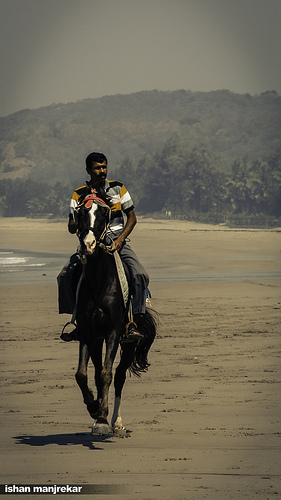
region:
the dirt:
[158, 381, 274, 474]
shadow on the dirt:
[15, 430, 80, 456]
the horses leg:
[73, 368, 132, 434]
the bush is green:
[154, 147, 230, 198]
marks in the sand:
[171, 319, 260, 417]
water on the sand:
[6, 255, 41, 277]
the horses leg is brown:
[100, 356, 116, 424]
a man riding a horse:
[72, 149, 124, 208]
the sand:
[181, 246, 257, 272]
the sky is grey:
[113, 57, 192, 78]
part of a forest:
[239, 177, 245, 190]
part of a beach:
[170, 442, 180, 459]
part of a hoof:
[110, 424, 113, 431]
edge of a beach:
[172, 425, 182, 456]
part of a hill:
[169, 456, 177, 472]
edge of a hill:
[184, 423, 200, 463]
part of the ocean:
[187, 408, 191, 414]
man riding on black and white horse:
[49, 148, 156, 439]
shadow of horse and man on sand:
[8, 430, 111, 457]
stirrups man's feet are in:
[59, 316, 140, 342]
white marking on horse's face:
[83, 200, 101, 232]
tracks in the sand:
[10, 307, 276, 474]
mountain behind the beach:
[14, 79, 280, 188]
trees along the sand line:
[11, 147, 276, 222]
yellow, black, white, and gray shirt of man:
[67, 185, 132, 241]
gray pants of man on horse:
[53, 233, 150, 314]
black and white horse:
[55, 187, 165, 433]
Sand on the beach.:
[0, 216, 280, 498]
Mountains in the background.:
[1, 86, 280, 218]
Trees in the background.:
[108, 129, 278, 226]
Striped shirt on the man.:
[65, 151, 137, 246]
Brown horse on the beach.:
[62, 187, 153, 439]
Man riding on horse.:
[52, 148, 163, 437]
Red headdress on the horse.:
[75, 189, 109, 217]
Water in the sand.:
[0, 240, 63, 280]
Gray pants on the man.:
[53, 151, 150, 320]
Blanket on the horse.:
[111, 240, 130, 307]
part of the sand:
[246, 436, 253, 486]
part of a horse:
[138, 357, 147, 365]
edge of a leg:
[103, 409, 105, 415]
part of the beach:
[188, 426, 195, 453]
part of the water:
[202, 451, 210, 469]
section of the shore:
[178, 466, 184, 482]